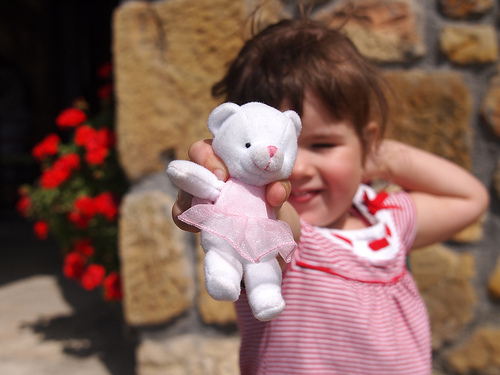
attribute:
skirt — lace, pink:
[175, 207, 296, 264]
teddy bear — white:
[165, 102, 303, 319]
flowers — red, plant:
[32, 103, 132, 280]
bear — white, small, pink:
[167, 100, 302, 321]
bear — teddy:
[155, 91, 322, 329]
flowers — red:
[17, 64, 118, 304]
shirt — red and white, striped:
[234, 190, 431, 373]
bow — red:
[355, 194, 395, 220]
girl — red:
[168, 9, 493, 371]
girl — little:
[152, 60, 481, 345]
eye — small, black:
[244, 140, 251, 150]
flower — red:
[43, 100, 122, 152]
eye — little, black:
[234, 132, 256, 150]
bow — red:
[362, 190, 404, 216]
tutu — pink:
[175, 172, 298, 263]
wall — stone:
[106, 8, 484, 373]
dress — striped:
[259, 185, 459, 367]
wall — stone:
[76, 47, 202, 349]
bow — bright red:
[355, 184, 403, 216]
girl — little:
[202, 8, 464, 364]